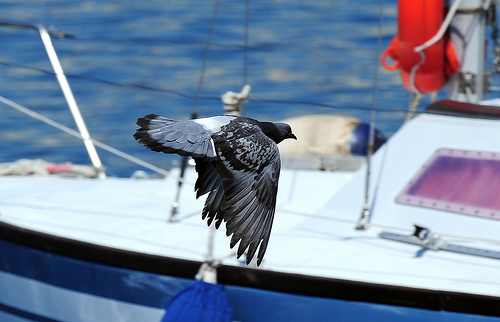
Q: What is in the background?
A: A boat.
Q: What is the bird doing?
A: Flying.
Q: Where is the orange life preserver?
A: On the boat.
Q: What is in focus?
A: The bird.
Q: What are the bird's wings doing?
A: Flapping.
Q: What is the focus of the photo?
A: The bird.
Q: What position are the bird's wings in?
A: Downward.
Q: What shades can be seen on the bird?
A: Black, white and gray.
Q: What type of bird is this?
A: A seagull.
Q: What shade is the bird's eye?
A: Red.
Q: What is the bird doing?
A: It is flying.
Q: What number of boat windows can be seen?
A: One.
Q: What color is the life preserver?
A: Orange.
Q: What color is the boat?
A: White.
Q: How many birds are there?
A: 1.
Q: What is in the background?
A: Boat.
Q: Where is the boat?
A: In the water.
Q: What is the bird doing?
A: Flying.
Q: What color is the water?
A: Blue.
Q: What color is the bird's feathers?
A: Gray and black.